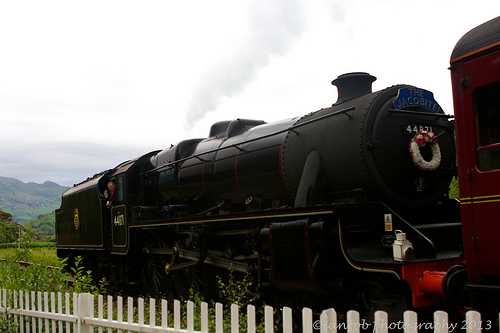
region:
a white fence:
[127, 300, 230, 324]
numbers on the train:
[400, 122, 440, 134]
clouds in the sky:
[67, 59, 146, 99]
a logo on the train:
[68, 208, 85, 232]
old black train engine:
[43, 91, 430, 266]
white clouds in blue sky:
[113, 58, 154, 79]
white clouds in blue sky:
[117, 31, 144, 62]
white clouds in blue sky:
[252, 36, 312, 90]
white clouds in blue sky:
[122, 31, 149, 75]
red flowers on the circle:
[407, 124, 452, 151]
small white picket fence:
[16, 272, 137, 319]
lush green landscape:
[11, 235, 48, 255]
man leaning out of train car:
[96, 177, 116, 194]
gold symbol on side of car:
[62, 200, 90, 227]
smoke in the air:
[161, 29, 291, 100]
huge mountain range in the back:
[11, 166, 50, 223]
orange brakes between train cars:
[391, 253, 474, 293]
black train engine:
[71, 80, 474, 295]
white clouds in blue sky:
[34, 6, 80, 44]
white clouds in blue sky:
[146, 34, 191, 56]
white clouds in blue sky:
[34, 89, 81, 125]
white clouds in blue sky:
[188, 36, 233, 76]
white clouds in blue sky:
[128, 21, 183, 71]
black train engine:
[45, 78, 467, 299]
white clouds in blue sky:
[12, 76, 76, 133]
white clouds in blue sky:
[112, 46, 164, 87]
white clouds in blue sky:
[169, 13, 247, 55]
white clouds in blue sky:
[310, 3, 381, 47]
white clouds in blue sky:
[97, 31, 152, 89]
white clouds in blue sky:
[69, 55, 136, 99]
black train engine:
[70, 73, 449, 300]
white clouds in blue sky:
[231, 46, 254, 72]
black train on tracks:
[27, 37, 487, 306]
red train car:
[431, 7, 498, 316]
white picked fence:
[13, 275, 493, 332]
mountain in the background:
[3, 161, 96, 252]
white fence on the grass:
[9, 299, 160, 326]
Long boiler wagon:
[159, 159, 399, 196]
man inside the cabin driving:
[101, 177, 128, 196]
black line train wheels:
[77, 260, 279, 288]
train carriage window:
[468, 83, 497, 170]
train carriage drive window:
[116, 180, 127, 202]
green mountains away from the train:
[4, 183, 59, 214]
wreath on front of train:
[410, 129, 442, 171]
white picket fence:
[2, 282, 497, 331]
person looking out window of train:
[95, 179, 120, 209]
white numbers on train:
[404, 122, 435, 134]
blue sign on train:
[392, 86, 441, 116]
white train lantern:
[387, 227, 413, 264]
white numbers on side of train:
[109, 212, 126, 228]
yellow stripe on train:
[455, 195, 498, 205]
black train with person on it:
[50, 70, 455, 302]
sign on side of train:
[70, 207, 81, 232]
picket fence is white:
[1, 285, 497, 330]